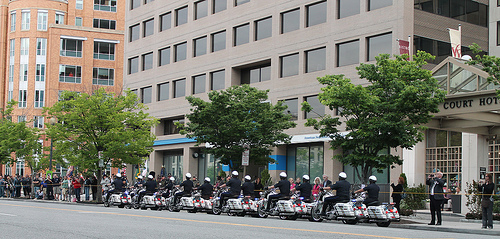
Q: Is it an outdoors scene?
A: Yes, it is outdoors.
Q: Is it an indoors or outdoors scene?
A: It is outdoors.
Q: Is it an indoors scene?
A: No, it is outdoors.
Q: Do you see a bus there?
A: No, there are no buses.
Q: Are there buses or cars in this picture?
A: No, there are no buses or cars.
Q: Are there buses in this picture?
A: No, there are no buses.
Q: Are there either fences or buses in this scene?
A: No, there are no buses or fences.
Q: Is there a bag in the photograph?
A: No, there are no bags.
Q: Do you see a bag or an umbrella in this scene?
A: No, there are no bags or umbrellas.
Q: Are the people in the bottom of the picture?
A: Yes, the people are in the bottom of the image.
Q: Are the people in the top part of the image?
A: No, the people are in the bottom of the image.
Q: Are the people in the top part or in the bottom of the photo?
A: The people are in the bottom of the image.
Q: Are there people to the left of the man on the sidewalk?
A: Yes, there are people to the left of the man.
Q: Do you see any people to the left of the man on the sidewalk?
A: Yes, there are people to the left of the man.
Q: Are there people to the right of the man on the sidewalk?
A: No, the people are to the left of the man.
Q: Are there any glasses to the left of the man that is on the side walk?
A: No, there are people to the left of the man.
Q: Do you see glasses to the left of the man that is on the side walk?
A: No, there are people to the left of the man.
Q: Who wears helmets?
A: The people wear helmets.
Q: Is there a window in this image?
A: Yes, there are windows.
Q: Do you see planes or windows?
A: Yes, there are windows.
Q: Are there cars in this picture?
A: No, there are no cars.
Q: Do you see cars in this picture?
A: No, there are no cars.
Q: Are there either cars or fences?
A: No, there are no cars or fences.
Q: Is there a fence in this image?
A: No, there are no fences.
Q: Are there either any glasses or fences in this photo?
A: No, there are no fences or glasses.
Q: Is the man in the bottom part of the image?
A: Yes, the man is in the bottom of the image.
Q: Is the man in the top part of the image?
A: No, the man is in the bottom of the image.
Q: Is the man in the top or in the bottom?
A: The man is in the bottom of the image.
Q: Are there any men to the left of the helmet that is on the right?
A: Yes, there is a man to the left of the helmet.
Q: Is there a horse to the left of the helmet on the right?
A: No, there is a man to the left of the helmet.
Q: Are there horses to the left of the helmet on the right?
A: No, there is a man to the left of the helmet.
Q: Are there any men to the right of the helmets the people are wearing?
A: Yes, there is a man to the right of the helmets.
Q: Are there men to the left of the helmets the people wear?
A: No, the man is to the right of the helmets.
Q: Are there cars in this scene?
A: No, there are no cars.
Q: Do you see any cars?
A: No, there are no cars.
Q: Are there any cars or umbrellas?
A: No, there are no cars or umbrellas.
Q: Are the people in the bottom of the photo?
A: Yes, the people are in the bottom of the image.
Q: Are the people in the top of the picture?
A: No, the people are in the bottom of the image.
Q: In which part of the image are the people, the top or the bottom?
A: The people are in the bottom of the image.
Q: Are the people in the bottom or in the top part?
A: The people are in the bottom of the image.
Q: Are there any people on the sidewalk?
A: Yes, there are people on the sidewalk.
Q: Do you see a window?
A: Yes, there is a window.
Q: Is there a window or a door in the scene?
A: Yes, there is a window.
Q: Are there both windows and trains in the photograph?
A: No, there is a window but no trains.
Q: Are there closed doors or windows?
A: Yes, there is a closed window.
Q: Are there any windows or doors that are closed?
A: Yes, the window is closed.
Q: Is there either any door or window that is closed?
A: Yes, the window is closed.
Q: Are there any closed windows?
A: Yes, there is a closed window.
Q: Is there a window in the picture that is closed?
A: Yes, there is a window that is closed.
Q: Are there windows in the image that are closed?
A: Yes, there is a window that is closed.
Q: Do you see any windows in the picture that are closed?
A: Yes, there is a window that is closed.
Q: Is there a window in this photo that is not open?
A: Yes, there is an closed window.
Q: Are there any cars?
A: No, there are no cars.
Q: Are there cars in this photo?
A: No, there are no cars.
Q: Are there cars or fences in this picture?
A: No, there are no cars or fences.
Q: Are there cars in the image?
A: No, there are no cars.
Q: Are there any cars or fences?
A: No, there are no cars or fences.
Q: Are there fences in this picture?
A: No, there are no fences.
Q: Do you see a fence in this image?
A: No, there are no fences.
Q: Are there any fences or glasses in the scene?
A: No, there are no fences or glasses.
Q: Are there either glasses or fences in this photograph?
A: No, there are no fences or glasses.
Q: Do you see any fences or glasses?
A: No, there are no fences or glasses.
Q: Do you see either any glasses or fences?
A: No, there are no fences or glasses.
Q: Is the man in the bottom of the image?
A: Yes, the man is in the bottom of the image.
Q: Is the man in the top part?
A: No, the man is in the bottom of the image.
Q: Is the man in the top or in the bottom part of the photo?
A: The man is in the bottom of the image.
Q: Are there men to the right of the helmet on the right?
A: Yes, there is a man to the right of the helmet.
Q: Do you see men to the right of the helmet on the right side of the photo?
A: Yes, there is a man to the right of the helmet.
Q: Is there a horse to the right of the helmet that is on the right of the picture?
A: No, there is a man to the right of the helmet.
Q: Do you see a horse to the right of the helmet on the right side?
A: No, there is a man to the right of the helmet.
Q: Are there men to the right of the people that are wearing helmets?
A: Yes, there is a man to the right of the people.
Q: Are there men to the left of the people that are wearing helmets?
A: No, the man is to the right of the people.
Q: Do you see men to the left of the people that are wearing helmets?
A: No, the man is to the right of the people.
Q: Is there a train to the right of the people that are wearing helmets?
A: No, there is a man to the right of the people.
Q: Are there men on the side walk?
A: Yes, there is a man on the side walk.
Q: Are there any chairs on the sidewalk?
A: No, there is a man on the sidewalk.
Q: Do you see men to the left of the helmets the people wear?
A: No, the man is to the right of the helmets.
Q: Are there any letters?
A: Yes, there are letters.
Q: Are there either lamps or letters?
A: Yes, there are letters.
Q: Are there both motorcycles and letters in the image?
A: Yes, there are both letters and a motorcycle.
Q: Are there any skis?
A: No, there are no skis.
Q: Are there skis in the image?
A: No, there are no skis.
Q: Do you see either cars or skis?
A: No, there are no skis or cars.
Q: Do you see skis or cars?
A: No, there are no skis or cars.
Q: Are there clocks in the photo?
A: No, there are no clocks.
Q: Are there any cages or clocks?
A: No, there are no clocks or cages.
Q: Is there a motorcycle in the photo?
A: Yes, there are motorcycles.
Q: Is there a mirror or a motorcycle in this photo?
A: Yes, there are motorcycles.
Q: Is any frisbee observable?
A: No, there are no frisbees.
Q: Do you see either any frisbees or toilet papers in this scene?
A: No, there are no frisbees or toilet papers.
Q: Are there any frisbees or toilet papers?
A: No, there are no frisbees or toilet papers.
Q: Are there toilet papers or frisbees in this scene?
A: No, there are no frisbees or toilet papers.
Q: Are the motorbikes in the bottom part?
A: Yes, the motorbikes are in the bottom of the image.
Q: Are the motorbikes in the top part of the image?
A: No, the motorbikes are in the bottom of the image.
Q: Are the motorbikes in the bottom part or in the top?
A: The motorbikes are in the bottom of the image.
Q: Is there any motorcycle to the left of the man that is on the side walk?
A: Yes, there are motorcycles to the left of the man.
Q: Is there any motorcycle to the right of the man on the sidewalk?
A: No, the motorcycles are to the left of the man.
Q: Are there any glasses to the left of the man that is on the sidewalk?
A: No, there are motorcycles to the left of the man.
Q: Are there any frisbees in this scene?
A: No, there are no frisbees.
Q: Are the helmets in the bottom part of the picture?
A: Yes, the helmets are in the bottom of the image.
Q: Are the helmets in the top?
A: No, the helmets are in the bottom of the image.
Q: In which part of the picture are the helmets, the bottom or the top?
A: The helmets are in the bottom of the image.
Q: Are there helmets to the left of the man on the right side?
A: Yes, there are helmets to the left of the man.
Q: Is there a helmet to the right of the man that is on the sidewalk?
A: No, the helmets are to the left of the man.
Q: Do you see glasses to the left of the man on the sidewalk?
A: No, there are helmets to the left of the man.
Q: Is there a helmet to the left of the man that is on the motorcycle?
A: Yes, there are helmets to the left of the man.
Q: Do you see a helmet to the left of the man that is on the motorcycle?
A: Yes, there are helmets to the left of the man.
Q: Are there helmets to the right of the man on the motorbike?
A: No, the helmets are to the left of the man.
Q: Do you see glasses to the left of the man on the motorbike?
A: No, there are helmets to the left of the man.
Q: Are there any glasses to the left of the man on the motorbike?
A: No, there are helmets to the left of the man.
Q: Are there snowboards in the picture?
A: No, there are no snowboards.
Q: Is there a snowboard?
A: No, there are no snowboards.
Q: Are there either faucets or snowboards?
A: No, there are no snowboards or faucets.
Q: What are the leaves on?
A: The leaves are on the trees.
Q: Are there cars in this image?
A: No, there are no cars.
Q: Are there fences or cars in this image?
A: No, there are no cars or fences.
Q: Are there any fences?
A: No, there are no fences.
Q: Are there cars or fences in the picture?
A: No, there are no fences or cars.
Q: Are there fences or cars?
A: No, there are no fences or cars.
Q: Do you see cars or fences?
A: No, there are no fences or cars.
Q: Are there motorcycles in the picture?
A: Yes, there is a motorcycle.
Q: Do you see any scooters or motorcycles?
A: Yes, there is a motorcycle.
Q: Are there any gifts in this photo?
A: No, there are no gifts.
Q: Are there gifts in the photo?
A: No, there are no gifts.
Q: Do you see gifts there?
A: No, there are no gifts.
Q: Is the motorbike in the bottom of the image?
A: Yes, the motorbike is in the bottom of the image.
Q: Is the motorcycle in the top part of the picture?
A: No, the motorcycle is in the bottom of the image.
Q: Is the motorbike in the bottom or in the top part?
A: The motorbike is in the bottom of the image.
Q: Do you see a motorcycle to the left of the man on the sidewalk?
A: Yes, there is a motorcycle to the left of the man.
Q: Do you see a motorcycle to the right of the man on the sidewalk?
A: No, the motorcycle is to the left of the man.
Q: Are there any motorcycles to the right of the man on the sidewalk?
A: No, the motorcycle is to the left of the man.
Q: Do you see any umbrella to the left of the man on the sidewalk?
A: No, there is a motorcycle to the left of the man.